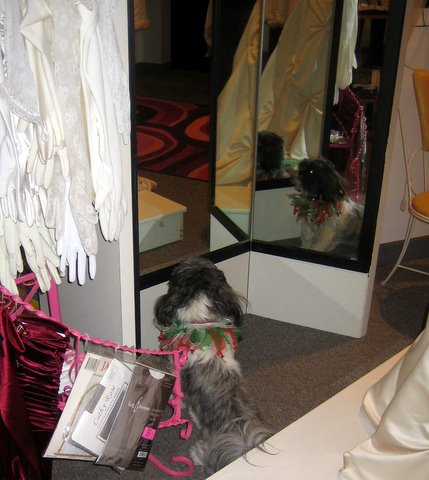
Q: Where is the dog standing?
A: In front of the mirror.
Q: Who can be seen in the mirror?
A: A dog.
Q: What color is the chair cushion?
A: Yellow.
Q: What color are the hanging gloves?
A: White.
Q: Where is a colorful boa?
A: Around the neck of the dog.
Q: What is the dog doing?
A: Sitting.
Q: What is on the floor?
A: Carpet.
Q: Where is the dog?
A: In front of the mirror.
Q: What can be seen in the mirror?
A: Reflection of the dog.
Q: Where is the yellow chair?
A: Against the wall.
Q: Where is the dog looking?
A: At the mirror.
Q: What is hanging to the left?
A: Clothes.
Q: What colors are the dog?
A: Gray and white.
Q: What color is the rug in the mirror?
A: Brown and red.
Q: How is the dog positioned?
A: Sitting.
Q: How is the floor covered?
A: Carpet.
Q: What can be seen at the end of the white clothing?
A: Gloves.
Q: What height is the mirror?
A: Tall.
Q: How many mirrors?
A: Two.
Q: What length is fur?
A: Long.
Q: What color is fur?
A: Black and white.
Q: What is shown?
A: A pet.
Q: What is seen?
A: Mirror.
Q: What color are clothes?
A: White.